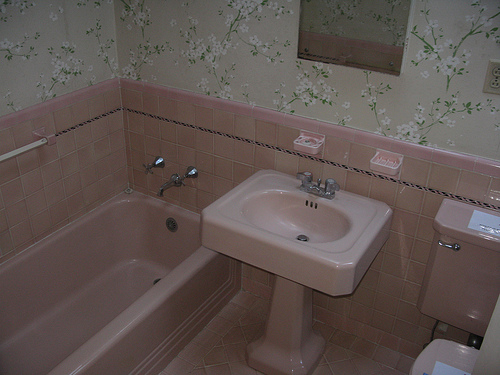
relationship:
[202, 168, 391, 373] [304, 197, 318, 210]
sink has slots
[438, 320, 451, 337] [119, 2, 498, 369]
outlet on wall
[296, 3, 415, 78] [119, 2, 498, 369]
mirror on wall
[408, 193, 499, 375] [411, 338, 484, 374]
toilet has a lid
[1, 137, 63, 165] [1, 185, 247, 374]
towel rack on bath tub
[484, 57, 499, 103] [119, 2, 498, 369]
electrical socket on wall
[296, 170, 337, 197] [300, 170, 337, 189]
faucet has handles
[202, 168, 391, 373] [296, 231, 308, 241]
sink has a drain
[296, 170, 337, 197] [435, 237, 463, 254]
faucet has handle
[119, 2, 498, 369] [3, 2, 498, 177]
wall has wallpaper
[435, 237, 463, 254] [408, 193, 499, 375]
handle on toilet